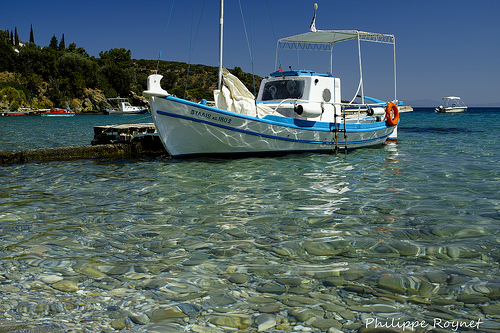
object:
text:
[363, 316, 369, 330]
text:
[395, 311, 405, 331]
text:
[405, 319, 406, 329]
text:
[432, 314, 487, 332]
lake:
[20, 110, 470, 320]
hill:
[13, 31, 225, 109]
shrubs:
[23, 78, 101, 103]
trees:
[52, 48, 99, 82]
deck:
[90, 119, 156, 144]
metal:
[8, 143, 129, 156]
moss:
[3, 147, 145, 161]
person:
[364, 312, 483, 332]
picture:
[9, 17, 485, 319]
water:
[18, 130, 451, 330]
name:
[190, 109, 232, 123]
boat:
[135, 0, 405, 157]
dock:
[91, 122, 158, 149]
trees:
[28, 21, 35, 47]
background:
[14, 22, 262, 113]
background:
[405, 58, 485, 134]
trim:
[273, 67, 334, 78]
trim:
[159, 108, 390, 148]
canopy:
[274, 14, 394, 106]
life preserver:
[385, 101, 400, 126]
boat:
[434, 96, 469, 114]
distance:
[413, 62, 479, 118]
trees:
[49, 33, 59, 51]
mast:
[218, 0, 227, 90]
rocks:
[142, 285, 193, 322]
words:
[190, 109, 232, 124]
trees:
[93, 58, 136, 97]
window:
[322, 88, 332, 101]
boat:
[40, 105, 76, 117]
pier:
[2, 134, 158, 166]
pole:
[215, 0, 227, 92]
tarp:
[218, 66, 286, 121]